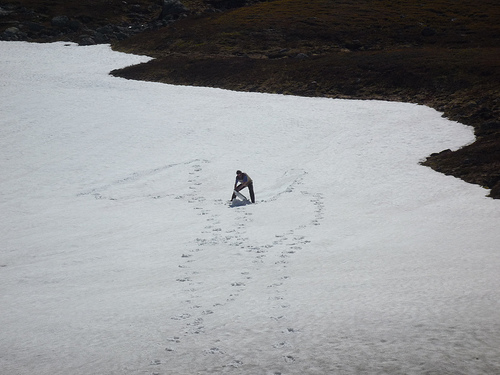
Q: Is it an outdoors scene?
A: Yes, it is outdoors.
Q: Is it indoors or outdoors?
A: It is outdoors.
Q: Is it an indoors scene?
A: No, it is outdoors.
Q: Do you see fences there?
A: No, there are no fences.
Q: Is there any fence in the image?
A: No, there are no fences.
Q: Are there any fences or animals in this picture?
A: No, there are no fences or animals.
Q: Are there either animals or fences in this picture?
A: No, there are no fences or animals.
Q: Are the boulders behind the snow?
A: Yes, the boulders are behind the snow.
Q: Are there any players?
A: No, there are no players.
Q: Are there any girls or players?
A: No, there are no players or girls.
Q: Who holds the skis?
A: The man holds the skis.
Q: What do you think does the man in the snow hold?
A: The man holds the skis.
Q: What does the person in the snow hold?
A: The man holds the skis.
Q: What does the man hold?
A: The man holds the skis.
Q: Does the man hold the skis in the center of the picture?
A: Yes, the man holds the skis.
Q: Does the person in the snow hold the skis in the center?
A: Yes, the man holds the skis.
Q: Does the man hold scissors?
A: No, the man holds the skis.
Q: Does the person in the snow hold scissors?
A: No, the man holds the skis.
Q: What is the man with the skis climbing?
A: The man is climbing the mountain.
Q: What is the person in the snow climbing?
A: The man is climbing the mountain.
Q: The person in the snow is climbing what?
A: The man is climbing the mountain.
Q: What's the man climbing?
A: The man is climbing the mountain.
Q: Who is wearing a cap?
A: The man is wearing a cap.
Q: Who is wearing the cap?
A: The man is wearing a cap.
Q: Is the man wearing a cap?
A: Yes, the man is wearing a cap.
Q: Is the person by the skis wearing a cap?
A: Yes, the man is wearing a cap.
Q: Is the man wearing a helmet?
A: No, the man is wearing a cap.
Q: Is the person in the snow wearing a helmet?
A: No, the man is wearing a cap.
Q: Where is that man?
A: The man is in the snow.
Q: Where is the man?
A: The man is in the snow.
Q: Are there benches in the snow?
A: No, there is a man in the snow.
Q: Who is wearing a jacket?
A: The man is wearing a jacket.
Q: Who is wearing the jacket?
A: The man is wearing a jacket.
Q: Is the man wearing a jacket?
A: Yes, the man is wearing a jacket.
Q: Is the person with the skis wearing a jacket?
A: Yes, the man is wearing a jacket.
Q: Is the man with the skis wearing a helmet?
A: No, the man is wearing a jacket.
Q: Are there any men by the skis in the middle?
A: Yes, there is a man by the skis.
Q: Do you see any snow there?
A: Yes, there is snow.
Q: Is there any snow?
A: Yes, there is snow.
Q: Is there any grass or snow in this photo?
A: Yes, there is snow.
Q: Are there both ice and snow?
A: No, there is snow but no ice.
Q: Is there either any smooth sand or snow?
A: Yes, there is smooth snow.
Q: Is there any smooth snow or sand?
A: Yes, there is smooth snow.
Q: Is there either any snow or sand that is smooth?
A: Yes, the snow is smooth.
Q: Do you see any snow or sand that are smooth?
A: Yes, the snow is smooth.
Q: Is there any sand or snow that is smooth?
A: Yes, the snow is smooth.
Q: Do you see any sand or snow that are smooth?
A: Yes, the snow is smooth.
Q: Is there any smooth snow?
A: Yes, there is smooth snow.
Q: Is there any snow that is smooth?
A: Yes, there is snow that is smooth.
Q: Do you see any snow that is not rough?
A: Yes, there is smooth snow.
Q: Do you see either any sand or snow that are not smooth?
A: No, there is snow but it is smooth.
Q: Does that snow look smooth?
A: Yes, the snow is smooth.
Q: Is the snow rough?
A: No, the snow is smooth.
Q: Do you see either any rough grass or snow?
A: No, there is snow but it is smooth.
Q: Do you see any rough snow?
A: No, there is snow but it is smooth.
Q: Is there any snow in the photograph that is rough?
A: No, there is snow but it is smooth.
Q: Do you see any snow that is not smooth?
A: No, there is snow but it is smooth.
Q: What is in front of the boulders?
A: The snow is in front of the boulders.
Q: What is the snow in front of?
A: The snow is in front of the boulders.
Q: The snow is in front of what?
A: The snow is in front of the boulders.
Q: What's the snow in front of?
A: The snow is in front of the boulders.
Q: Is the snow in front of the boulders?
A: Yes, the snow is in front of the boulders.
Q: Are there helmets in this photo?
A: No, there are no helmets.